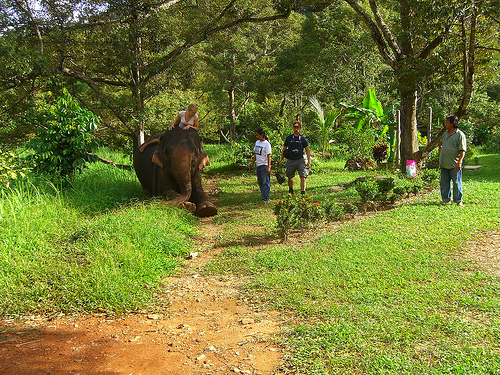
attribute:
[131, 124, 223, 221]
elephant — resting, tired, relaxed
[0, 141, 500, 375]
grass — green, patchy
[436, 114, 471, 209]
man — standing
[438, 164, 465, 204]
jeans — blue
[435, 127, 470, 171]
shirt — green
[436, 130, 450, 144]
sleeve — short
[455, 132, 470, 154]
sleeve — short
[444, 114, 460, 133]
hair — dark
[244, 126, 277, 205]
woman — standing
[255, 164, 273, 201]
jeans — blue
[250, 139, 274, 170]
shirt — white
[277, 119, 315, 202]
man — standing